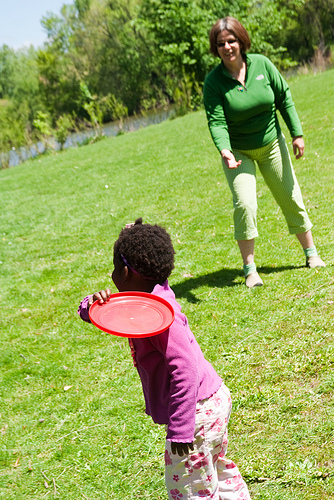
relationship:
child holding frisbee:
[83, 217, 245, 500] [85, 286, 175, 346]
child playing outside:
[83, 217, 245, 500] [2, 2, 331, 499]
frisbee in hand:
[85, 286, 175, 346] [90, 284, 114, 309]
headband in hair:
[109, 238, 167, 286] [111, 217, 177, 283]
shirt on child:
[73, 286, 227, 439] [79, 217, 249, 500]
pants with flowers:
[158, 392, 253, 497] [171, 395, 242, 500]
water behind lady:
[13, 89, 192, 171] [203, 18, 325, 289]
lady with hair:
[203, 18, 325, 289] [210, 17, 253, 59]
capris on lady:
[228, 133, 312, 244] [203, 18, 325, 289]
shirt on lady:
[201, 53, 302, 158] [203, 18, 325, 289]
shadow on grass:
[167, 262, 307, 304] [9, 68, 333, 491]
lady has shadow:
[203, 18, 325, 289] [167, 262, 307, 304]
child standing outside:
[83, 217, 245, 500] [2, 2, 331, 499]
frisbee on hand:
[85, 286, 175, 346] [90, 284, 114, 309]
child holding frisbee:
[79, 217, 249, 500] [85, 286, 175, 346]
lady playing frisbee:
[203, 18, 325, 289] [5, 0, 332, 492]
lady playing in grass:
[203, 18, 325, 289] [9, 68, 333, 491]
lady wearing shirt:
[202, 15, 314, 294] [203, 53, 302, 154]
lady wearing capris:
[203, 18, 325, 289] [228, 133, 312, 244]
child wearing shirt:
[79, 217, 249, 500] [76, 280, 222, 443]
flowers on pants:
[171, 395, 242, 500] [158, 392, 253, 497]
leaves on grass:
[24, 178, 127, 493] [9, 68, 333, 491]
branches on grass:
[252, 467, 327, 488] [9, 68, 333, 491]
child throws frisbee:
[79, 217, 249, 500] [85, 286, 175, 346]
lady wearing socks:
[203, 18, 325, 289] [241, 248, 323, 286]